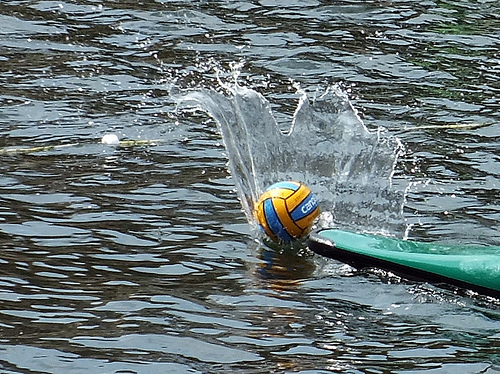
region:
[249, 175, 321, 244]
Volleyball in the water.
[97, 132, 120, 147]
White buoy in the water.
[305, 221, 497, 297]
green board in the water.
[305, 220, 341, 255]
black trim on the board.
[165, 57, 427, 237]
splash of water in the air.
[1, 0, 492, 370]
Water covering the surface.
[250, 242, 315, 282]
Reflection of ball in the water.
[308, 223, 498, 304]
black bottom on the board.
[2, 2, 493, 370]
Ripples in the water.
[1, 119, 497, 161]
Rope in the water.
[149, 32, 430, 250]
the water is splashing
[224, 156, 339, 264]
the ball made the water splash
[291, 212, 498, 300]
the end of a row boat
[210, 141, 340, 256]
the ball has blue and yellow panels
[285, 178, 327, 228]
the letters on the ball are white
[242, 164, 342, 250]
there are black lines on the ball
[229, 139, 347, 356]
the ball hit the surface of the water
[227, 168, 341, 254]
the ball is on the surface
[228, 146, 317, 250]
a ball in water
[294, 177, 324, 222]
white text in the ball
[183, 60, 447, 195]
water raising up from down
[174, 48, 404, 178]
flow of water to up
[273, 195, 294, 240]
a yellow color in ball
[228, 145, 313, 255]
a foot ball in water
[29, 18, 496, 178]
a clear view of water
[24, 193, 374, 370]
riddles in the water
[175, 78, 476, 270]
the ball splashes in the water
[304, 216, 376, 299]
the boat has a green tip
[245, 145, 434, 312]
the ball is yellow and blue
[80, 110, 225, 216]
a white ball is in the water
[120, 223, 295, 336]
the water ripples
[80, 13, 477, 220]
the water splashes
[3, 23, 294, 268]
the sun is shining on the water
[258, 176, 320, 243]
a yellow and blue ball in the water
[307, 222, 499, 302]
the front of a green boat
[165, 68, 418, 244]
a big water splash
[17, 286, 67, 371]
a bit murky water with some ripples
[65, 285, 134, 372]
a bit murky water with some ripples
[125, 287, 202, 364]
a bit murky water with some ripples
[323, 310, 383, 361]
a bit murky water with some ripples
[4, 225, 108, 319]
a bit murky water with some ripples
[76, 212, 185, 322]
a bit murky water with some ripples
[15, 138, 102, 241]
a bit murky water with some ripples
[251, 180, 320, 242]
ball in the water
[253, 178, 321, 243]
blue and yellow colored ball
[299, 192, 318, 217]
white letters on the ball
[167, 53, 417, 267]
splash of water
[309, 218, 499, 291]
green object in the water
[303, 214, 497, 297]
green object near the ball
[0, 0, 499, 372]
dark colored body of water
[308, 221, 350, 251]
black tip of a green object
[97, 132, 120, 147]
white object in the water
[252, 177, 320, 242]
ball floating in the water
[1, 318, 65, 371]
murky water with some ripples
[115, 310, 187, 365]
murky water with some ripples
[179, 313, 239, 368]
murky water with some ripples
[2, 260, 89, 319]
murky water with some ripples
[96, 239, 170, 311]
murky water with some ripples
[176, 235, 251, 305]
murky water with some ripples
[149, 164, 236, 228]
murky water with some ripples